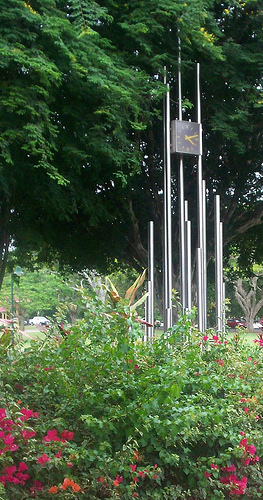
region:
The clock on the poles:
[166, 115, 203, 161]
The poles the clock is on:
[174, 5, 202, 339]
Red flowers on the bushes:
[0, 331, 261, 497]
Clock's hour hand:
[185, 135, 194, 145]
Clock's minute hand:
[183, 132, 198, 139]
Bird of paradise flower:
[99, 266, 153, 328]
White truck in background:
[26, 315, 51, 328]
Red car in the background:
[225, 313, 261, 329]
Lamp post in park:
[7, 265, 27, 348]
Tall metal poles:
[137, 28, 229, 348]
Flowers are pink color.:
[3, 401, 261, 489]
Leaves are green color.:
[69, 368, 192, 414]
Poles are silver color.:
[144, 226, 231, 315]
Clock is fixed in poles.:
[168, 117, 207, 163]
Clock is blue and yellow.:
[167, 115, 202, 155]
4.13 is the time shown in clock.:
[174, 116, 205, 159]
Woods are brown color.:
[116, 196, 150, 262]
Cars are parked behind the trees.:
[3, 305, 260, 333]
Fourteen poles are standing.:
[144, 209, 236, 297]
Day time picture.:
[22, 123, 251, 498]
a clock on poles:
[143, 48, 235, 347]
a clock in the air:
[113, 37, 231, 281]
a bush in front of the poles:
[0, 297, 251, 496]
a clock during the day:
[137, 71, 242, 305]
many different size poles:
[125, 132, 250, 356]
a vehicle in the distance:
[25, 312, 49, 336]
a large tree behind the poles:
[49, 192, 222, 350]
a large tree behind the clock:
[34, 104, 227, 338]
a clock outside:
[145, 80, 249, 244]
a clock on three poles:
[145, 96, 256, 241]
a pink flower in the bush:
[59, 427, 77, 440]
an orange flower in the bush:
[46, 475, 83, 493]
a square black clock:
[169, 112, 205, 156]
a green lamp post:
[7, 262, 23, 353]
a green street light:
[12, 264, 25, 279]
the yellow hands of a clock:
[182, 131, 197, 147]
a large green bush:
[0, 294, 262, 498]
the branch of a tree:
[115, 198, 164, 285]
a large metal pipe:
[141, 216, 162, 345]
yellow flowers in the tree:
[198, 24, 219, 46]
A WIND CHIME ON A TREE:
[147, 20, 231, 352]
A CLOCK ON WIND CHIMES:
[164, 115, 217, 181]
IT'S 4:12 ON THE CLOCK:
[157, 110, 212, 157]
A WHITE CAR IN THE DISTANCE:
[28, 307, 55, 328]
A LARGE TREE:
[10, 71, 253, 255]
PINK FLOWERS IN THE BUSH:
[1, 403, 77, 487]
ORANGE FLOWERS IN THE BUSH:
[43, 478, 96, 494]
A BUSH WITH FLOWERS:
[3, 318, 259, 491]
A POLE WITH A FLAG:
[5, 263, 29, 324]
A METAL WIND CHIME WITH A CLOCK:
[131, 30, 233, 355]